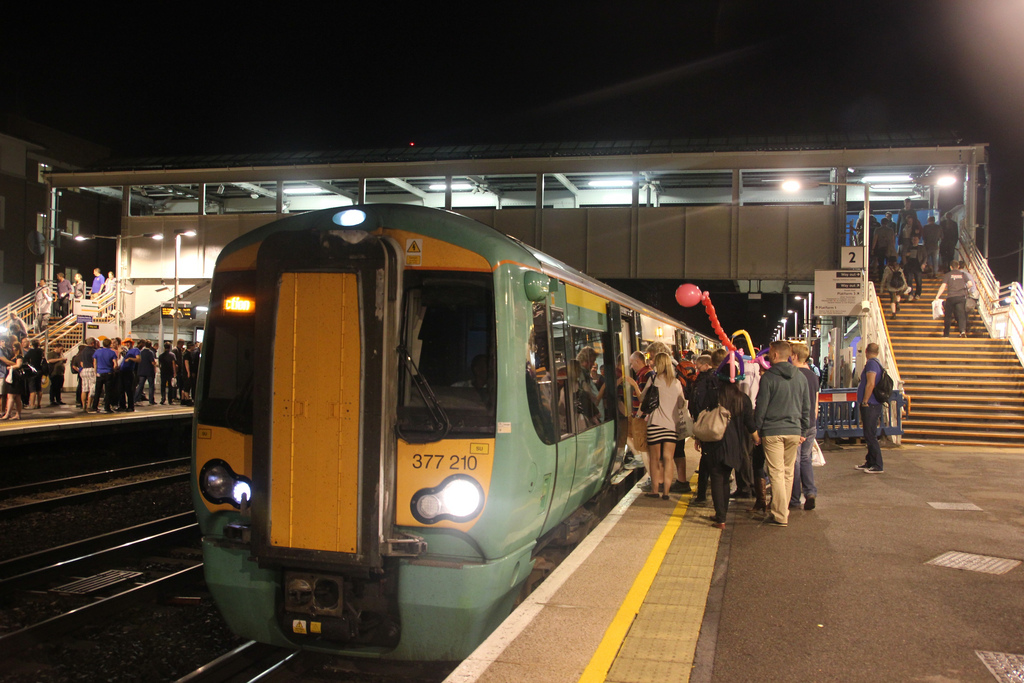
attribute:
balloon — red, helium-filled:
[672, 281, 734, 351]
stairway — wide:
[845, 261, 1014, 435]